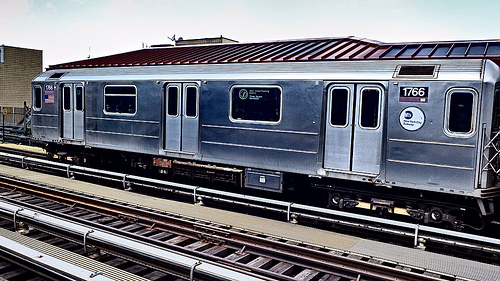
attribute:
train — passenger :
[19, 59, 490, 186]